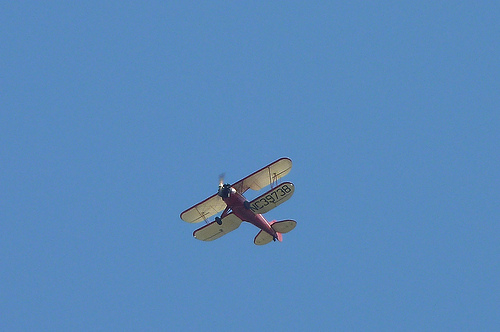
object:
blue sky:
[2, 1, 78, 35]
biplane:
[181, 157, 297, 246]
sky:
[379, 1, 456, 48]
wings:
[250, 156, 303, 206]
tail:
[255, 219, 299, 245]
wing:
[253, 180, 302, 212]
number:
[247, 185, 293, 211]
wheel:
[214, 215, 223, 227]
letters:
[252, 182, 296, 212]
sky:
[129, 11, 200, 51]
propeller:
[217, 172, 227, 193]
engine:
[224, 182, 235, 195]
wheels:
[242, 199, 252, 209]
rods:
[204, 164, 287, 225]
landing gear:
[213, 195, 253, 228]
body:
[222, 182, 272, 226]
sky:
[175, 82, 256, 130]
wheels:
[220, 197, 227, 202]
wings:
[178, 145, 299, 245]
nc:
[248, 199, 262, 211]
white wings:
[175, 189, 241, 242]